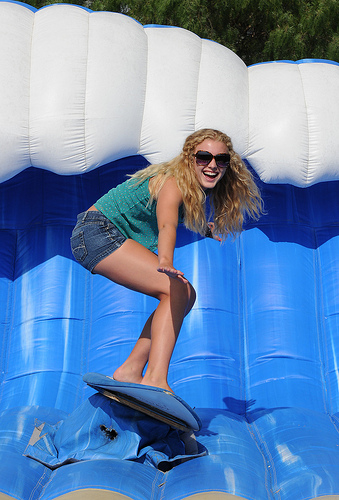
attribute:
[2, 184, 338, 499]
covering — blue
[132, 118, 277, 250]
hair — blonde, curly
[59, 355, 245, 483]
platform — fake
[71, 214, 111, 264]
shorts — blue, denim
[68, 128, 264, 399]
woman — crouched, white, dark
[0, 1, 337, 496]
tarp — ripped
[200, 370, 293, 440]
shadow — woman's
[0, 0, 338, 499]
jumper — blue, white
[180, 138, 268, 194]
sunglasses — large, dark, black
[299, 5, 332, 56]
tree — large green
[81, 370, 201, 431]
surfboard — soft, blue, fake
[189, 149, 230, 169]
sunglasses — large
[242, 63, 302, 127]
pads — large, white, inflatable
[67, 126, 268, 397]
girl — posing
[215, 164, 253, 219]
blonde hair — loose, long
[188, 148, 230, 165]
sunglasses — large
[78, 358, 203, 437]
surfboard — blue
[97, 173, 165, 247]
tank top — green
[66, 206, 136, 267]
shorts —  blue jean 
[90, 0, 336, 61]
tree leaves — green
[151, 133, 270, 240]
hair — curly, blonde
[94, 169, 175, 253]
shirt — green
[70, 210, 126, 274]
shorts — blue, jean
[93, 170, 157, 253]
tank top — teal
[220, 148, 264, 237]
hair — long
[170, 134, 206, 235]
hair — blonde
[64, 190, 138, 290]
shorts — short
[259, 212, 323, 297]
inflatable pads — giant, blue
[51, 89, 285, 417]
girl —  barefoot 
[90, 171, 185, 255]
top — green, sleeveless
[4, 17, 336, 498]
pad — blue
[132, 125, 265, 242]
hair — long, wavy, blonde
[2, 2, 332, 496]
inflatable — blue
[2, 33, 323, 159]
material — white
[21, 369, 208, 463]
simulator — surfing